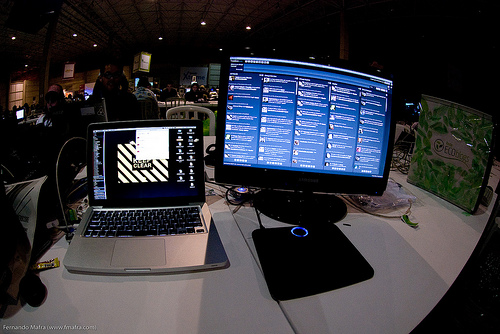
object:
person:
[189, 74, 198, 86]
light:
[68, 34, 80, 42]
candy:
[28, 260, 63, 271]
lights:
[152, 34, 166, 44]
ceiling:
[2, 3, 497, 71]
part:
[291, 224, 308, 236]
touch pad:
[251, 221, 374, 301]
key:
[90, 221, 100, 224]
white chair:
[161, 105, 221, 137]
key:
[164, 212, 171, 222]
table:
[204, 134, 499, 333]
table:
[0, 159, 300, 333]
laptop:
[61, 118, 232, 275]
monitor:
[222, 55, 391, 179]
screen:
[86, 125, 203, 203]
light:
[195, 15, 209, 29]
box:
[405, 95, 496, 215]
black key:
[158, 227, 169, 236]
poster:
[137, 50, 152, 72]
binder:
[405, 94, 492, 219]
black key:
[185, 225, 195, 232]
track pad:
[106, 236, 167, 269]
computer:
[214, 53, 403, 227]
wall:
[1, 47, 225, 113]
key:
[105, 209, 115, 218]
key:
[118, 209, 128, 217]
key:
[83, 225, 93, 238]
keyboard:
[81, 206, 207, 237]